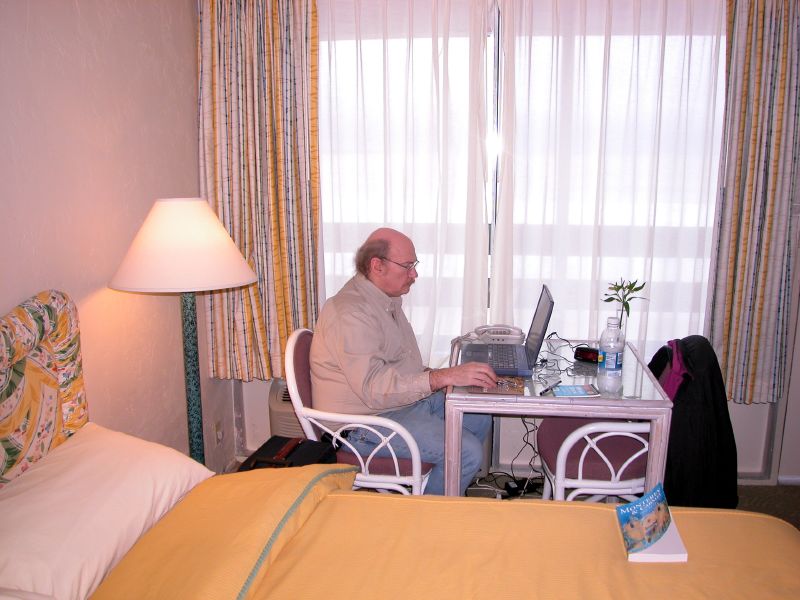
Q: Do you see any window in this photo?
A: Yes, there is a window.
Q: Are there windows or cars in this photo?
A: Yes, there is a window.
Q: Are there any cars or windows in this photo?
A: Yes, there is a window.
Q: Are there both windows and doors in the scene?
A: No, there is a window but no doors.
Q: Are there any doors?
A: No, there are no doors.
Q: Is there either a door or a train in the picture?
A: No, there are no doors or trains.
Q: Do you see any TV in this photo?
A: No, there are no televisions.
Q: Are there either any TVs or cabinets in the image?
A: No, there are no TVs or cabinets.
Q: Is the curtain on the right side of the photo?
A: Yes, the curtain is on the right of the image.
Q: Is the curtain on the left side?
A: No, the curtain is on the right of the image.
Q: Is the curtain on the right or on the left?
A: The curtain is on the right of the image.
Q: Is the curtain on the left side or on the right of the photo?
A: The curtain is on the right of the image.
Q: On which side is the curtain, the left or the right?
A: The curtain is on the right of the image.